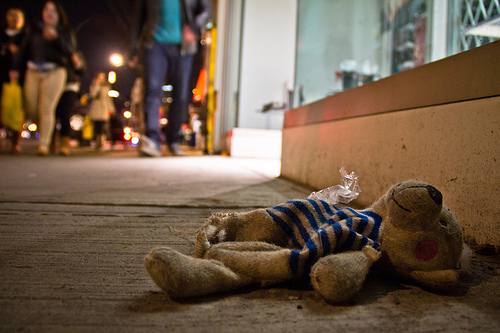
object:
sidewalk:
[0, 142, 500, 331]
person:
[1, 8, 31, 153]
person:
[86, 68, 116, 148]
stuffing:
[308, 167, 361, 203]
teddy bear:
[144, 166, 464, 304]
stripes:
[361, 210, 383, 247]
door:
[431, 0, 499, 62]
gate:
[448, 1, 498, 55]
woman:
[21, 0, 69, 152]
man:
[136, 1, 215, 157]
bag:
[66, 46, 81, 72]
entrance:
[229, 2, 297, 177]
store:
[221, 1, 499, 247]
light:
[106, 70, 118, 84]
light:
[106, 89, 122, 99]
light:
[121, 108, 133, 121]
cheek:
[414, 238, 439, 260]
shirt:
[152, 0, 184, 45]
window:
[292, 1, 500, 109]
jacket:
[126, 0, 208, 53]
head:
[374, 180, 477, 294]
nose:
[428, 185, 443, 203]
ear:
[412, 268, 459, 291]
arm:
[311, 250, 376, 290]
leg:
[179, 254, 241, 301]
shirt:
[265, 197, 387, 282]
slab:
[2, 201, 497, 327]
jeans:
[142, 42, 193, 146]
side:
[223, 0, 303, 133]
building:
[214, 1, 384, 164]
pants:
[25, 69, 67, 146]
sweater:
[12, 26, 77, 69]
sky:
[13, 4, 162, 87]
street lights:
[109, 51, 124, 68]